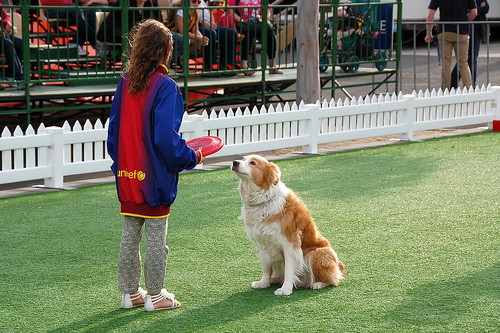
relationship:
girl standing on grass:
[92, 17, 210, 331] [0, 198, 460, 328]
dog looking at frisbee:
[228, 150, 348, 296] [183, 132, 222, 153]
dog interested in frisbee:
[228, 150, 348, 296] [183, 133, 224, 154]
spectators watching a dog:
[77, 2, 290, 74] [228, 150, 348, 296]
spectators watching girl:
[77, 2, 290, 74] [106, 17, 201, 312]